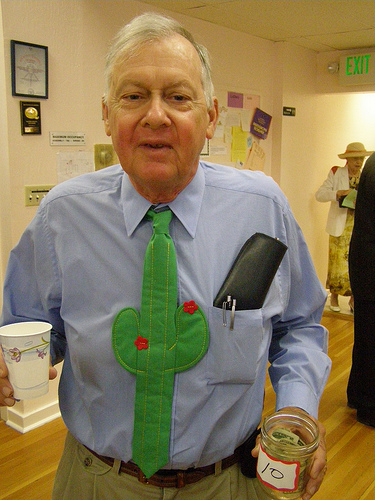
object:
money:
[259, 427, 304, 492]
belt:
[84, 443, 234, 488]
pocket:
[207, 307, 264, 386]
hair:
[101, 10, 215, 114]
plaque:
[10, 36, 49, 100]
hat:
[336, 138, 375, 161]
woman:
[314, 140, 375, 316]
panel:
[24, 186, 53, 207]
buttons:
[34, 192, 40, 203]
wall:
[3, 2, 274, 291]